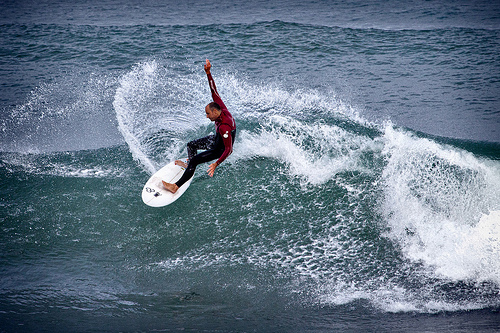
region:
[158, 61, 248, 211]
a man in colorful wet suit surfs on a tall wave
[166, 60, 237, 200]
a surfer wearing a red shirt balances on a white surfboard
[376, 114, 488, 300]
white waves spray water in a blue ocean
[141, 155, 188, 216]
a white surfboard with black logo sways underneath a surfer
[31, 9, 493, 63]
soft waves ripple in the blue sea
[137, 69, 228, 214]
a balding man balances on a surfboard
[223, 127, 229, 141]
a white logo sewn onto a red wet suit top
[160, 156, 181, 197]
two bare feet stabilize a leaning surfboard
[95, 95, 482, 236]
a huge wave crashes into a surfer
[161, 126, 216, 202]
slick, wet black pants cling to a man's legs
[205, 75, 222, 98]
white, vertical logo on surfer's red wetsuit sleeve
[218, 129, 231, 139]
white, apple-shaped logo on the shoulder of surfer's left, red wetsuit sleeve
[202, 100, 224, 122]
surfer is middle-aged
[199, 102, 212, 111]
surfer's hairline is receeding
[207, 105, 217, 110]
surfer's hair is grey at the temple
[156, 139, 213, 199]
surfer is adept & practiced at balancing on surfboard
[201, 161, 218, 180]
the fingers of surfer's left hand are spread to help him balance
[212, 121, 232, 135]
surfer's wetsuit seems to have a black shoulder strap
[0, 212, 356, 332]
ocean water goes from deep blue to dark teal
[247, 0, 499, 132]
ocean behind wave is slightly choppy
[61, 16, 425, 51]
Clear blue water behind the surfer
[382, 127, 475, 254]
White spray of the wave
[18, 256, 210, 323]
Calm blue water in front of the surfer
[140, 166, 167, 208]
White surfboard the surfer is riding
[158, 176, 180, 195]
Surfer's left foot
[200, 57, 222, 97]
Surfer's extended right arm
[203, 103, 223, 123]
Head of the man riding the surfboard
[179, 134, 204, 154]
Surfer's right knee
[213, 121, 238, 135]
Red top of the surfer's wetsuit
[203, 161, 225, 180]
Surfer's left hand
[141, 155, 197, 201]
the skateboard is white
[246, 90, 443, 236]
the waves are small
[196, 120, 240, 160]
the swimsuit is red and black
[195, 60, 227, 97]
the hand is in the air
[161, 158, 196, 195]
the feet are bare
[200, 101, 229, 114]
the man has black hair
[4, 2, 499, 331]
it is a daytime photo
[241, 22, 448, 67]
the water is calm in the background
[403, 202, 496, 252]
the splash wave is white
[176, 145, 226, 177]
the pants are black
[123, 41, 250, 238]
Man riding a surfboard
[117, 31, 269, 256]
Man wearing red and black body suit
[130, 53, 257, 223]
Man with no shoes on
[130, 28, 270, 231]
Man riding white surfboard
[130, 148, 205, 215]
White wooden surfboard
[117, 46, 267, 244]
Man riding surfboard on a wave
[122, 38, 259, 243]
Man with two feet on a surfboard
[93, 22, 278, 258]
Person riding surfboard on the water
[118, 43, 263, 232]
Person riding a wave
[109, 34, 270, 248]
Person wearing a bodysuit on a surfboard